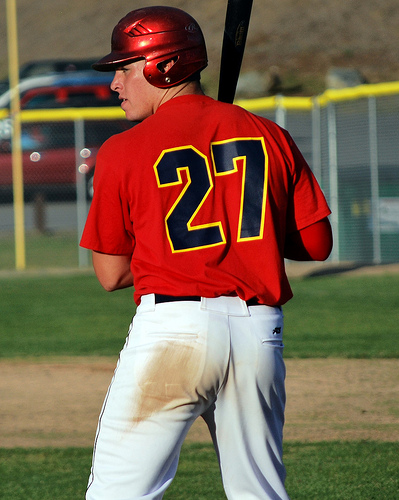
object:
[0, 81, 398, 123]
yellow trimming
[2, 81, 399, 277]
fence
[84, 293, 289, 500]
pants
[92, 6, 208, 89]
helmet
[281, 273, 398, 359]
grass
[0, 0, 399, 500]
baseball field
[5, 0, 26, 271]
pole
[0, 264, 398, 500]
field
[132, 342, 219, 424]
dirt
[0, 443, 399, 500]
grass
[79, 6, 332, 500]
man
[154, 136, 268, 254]
"27"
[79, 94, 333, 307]
jersey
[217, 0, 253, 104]
bat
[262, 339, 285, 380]
pocket